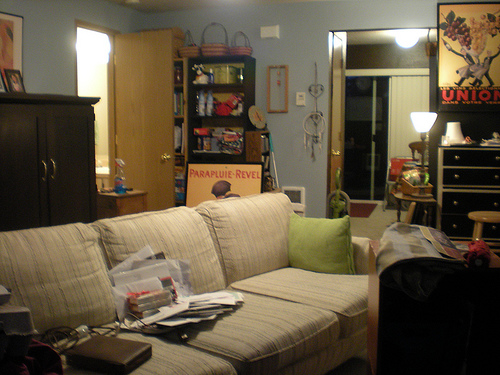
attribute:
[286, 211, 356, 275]
pillow — green fluffy 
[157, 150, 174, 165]
door knob — shiny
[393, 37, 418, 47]
globe — light 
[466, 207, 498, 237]
stool — brown wooden 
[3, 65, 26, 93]
frame — sitting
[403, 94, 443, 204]
lamp — bright free standing 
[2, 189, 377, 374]
sofa — light, beige 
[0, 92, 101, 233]
amoire —  black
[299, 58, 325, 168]
dream catcher — dream 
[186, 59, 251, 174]
book shelf —  top 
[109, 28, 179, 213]
door — light, brown, wooden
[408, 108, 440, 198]
lamp — small table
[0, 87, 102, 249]
doors — dark, brown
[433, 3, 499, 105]
poster — Union.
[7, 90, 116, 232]
tv stand — brown wooden TV 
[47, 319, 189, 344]
cords — black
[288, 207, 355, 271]
pillow — green 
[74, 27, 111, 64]
light — on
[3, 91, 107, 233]
dresser — dark brown 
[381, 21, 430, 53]
light — on, ceiling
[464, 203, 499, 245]
chair — wood 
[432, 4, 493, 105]
poster. — framed art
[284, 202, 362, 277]
pillow — green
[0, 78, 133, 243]
amoire —  black